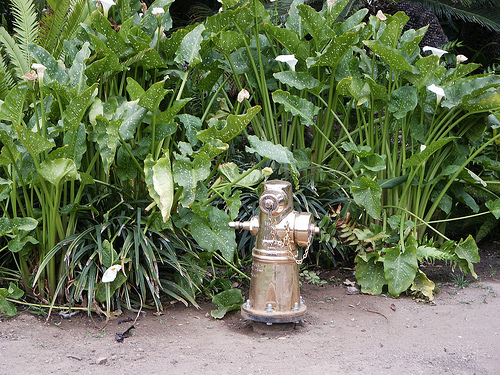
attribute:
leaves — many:
[4, 4, 486, 314]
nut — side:
[225, 217, 241, 229]